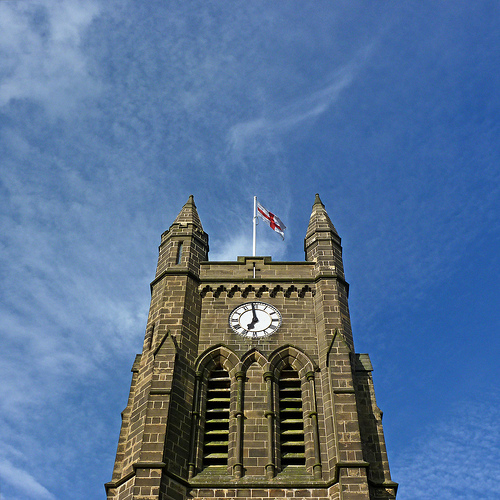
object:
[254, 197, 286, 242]
flag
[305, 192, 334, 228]
point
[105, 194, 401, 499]
building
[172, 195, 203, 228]
point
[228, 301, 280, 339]
clock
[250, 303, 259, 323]
minute hand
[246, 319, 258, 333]
hour hand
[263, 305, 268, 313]
number one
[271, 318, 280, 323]
number three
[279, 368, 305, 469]
window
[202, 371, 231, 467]
window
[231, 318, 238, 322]
roman numerals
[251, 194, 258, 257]
pole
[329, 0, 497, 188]
sky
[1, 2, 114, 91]
clouds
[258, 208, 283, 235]
cross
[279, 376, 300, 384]
slit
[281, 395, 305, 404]
slit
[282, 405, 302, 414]
slit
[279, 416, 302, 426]
slit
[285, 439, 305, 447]
slit